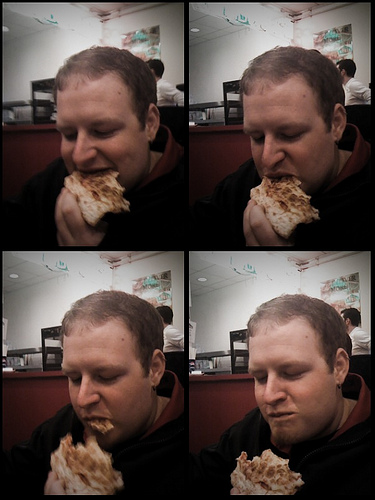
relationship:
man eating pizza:
[195, 47, 372, 247] [243, 173, 321, 236]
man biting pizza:
[195, 47, 372, 247] [243, 173, 321, 236]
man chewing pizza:
[28, 290, 183, 497] [58, 439, 128, 494]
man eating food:
[8, 45, 182, 247] [68, 163, 126, 227]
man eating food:
[8, 45, 182, 247] [65, 169, 130, 223]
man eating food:
[195, 47, 372, 247] [249, 176, 319, 238]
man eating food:
[28, 290, 183, 497] [51, 418, 123, 495]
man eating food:
[198, 292, 374, 496] [231, 447, 307, 498]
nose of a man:
[260, 131, 284, 167] [195, 47, 372, 247]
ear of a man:
[332, 346, 352, 385] [198, 292, 374, 496]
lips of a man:
[265, 409, 297, 420] [198, 292, 374, 496]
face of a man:
[55, 90, 149, 176] [28, 45, 186, 247]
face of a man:
[240, 94, 332, 179] [195, 47, 372, 247]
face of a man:
[60, 346, 148, 437] [5, 288, 183, 494]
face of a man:
[245, 347, 334, 442] [198, 292, 374, 496]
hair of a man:
[59, 286, 166, 371] [10, 269, 191, 495]